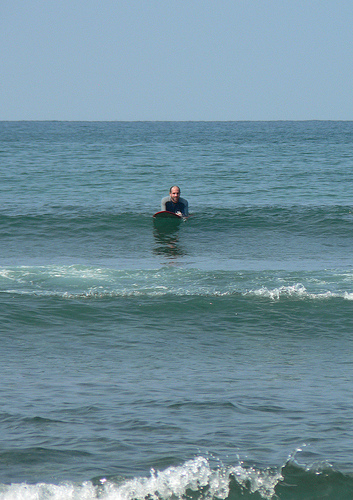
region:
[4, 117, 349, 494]
The water is blue.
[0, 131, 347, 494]
The water is wavy.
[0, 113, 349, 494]
The water is splashing.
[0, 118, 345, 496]
The water is ripply.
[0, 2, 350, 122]
The sky is blue.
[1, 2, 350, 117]
The sky is clear.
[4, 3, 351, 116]
The sky is cloudless.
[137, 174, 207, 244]
Man on a surfboard.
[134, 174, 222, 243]
Man is in the water.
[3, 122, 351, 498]
The water is engaging.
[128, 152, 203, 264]
man on a surfboard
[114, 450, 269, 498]
wave breaking near shore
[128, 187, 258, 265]
guy on a red surfboard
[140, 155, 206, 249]
guy laying on a surfboard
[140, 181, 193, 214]
man wearing blue and gray wet suit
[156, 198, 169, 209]
blue and gray we suit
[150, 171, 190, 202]
man with receding hair line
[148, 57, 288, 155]
gray sky over the water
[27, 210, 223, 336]
small waves forming in the water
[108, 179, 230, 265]
person laying on a board in the water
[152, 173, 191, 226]
surfer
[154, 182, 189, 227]
male surfer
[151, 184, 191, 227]
male surfer in ocean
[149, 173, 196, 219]
male surfer on surfboard in ocean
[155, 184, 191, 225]
male surfer on red surfboard in ocean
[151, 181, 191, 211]
male surfer wearing gray wet suit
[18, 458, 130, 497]
white and blue waves in ocean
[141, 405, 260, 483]
white and blue waves in ocean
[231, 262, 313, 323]
white and blue waves in ocean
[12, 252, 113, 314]
white and blue waves in ocean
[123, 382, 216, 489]
the water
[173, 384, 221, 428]
the water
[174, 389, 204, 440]
the water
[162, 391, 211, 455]
the water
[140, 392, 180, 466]
the water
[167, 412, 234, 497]
the water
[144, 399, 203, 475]
the water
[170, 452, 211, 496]
the water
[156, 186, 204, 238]
Man on a surf board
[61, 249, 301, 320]
Ocean waves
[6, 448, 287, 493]
A bigger wave closer to the shore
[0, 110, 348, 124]
The coastline beween the ocean and the sky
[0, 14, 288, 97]
A blue cloudless sky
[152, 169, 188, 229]
Man sitting on surf board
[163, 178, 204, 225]
Man waiting for a wave to ride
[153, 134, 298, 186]
Ripples in the water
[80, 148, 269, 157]
Water appears to be blue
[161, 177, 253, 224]
Man surfing alone